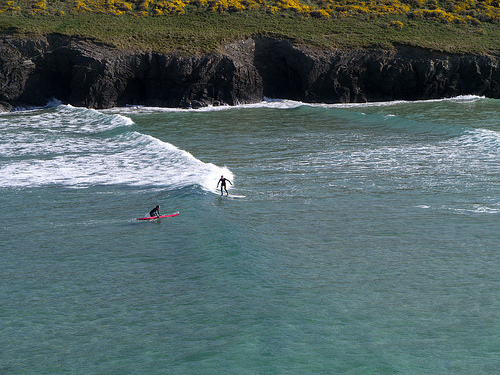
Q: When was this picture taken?
A: During the day.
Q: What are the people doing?
A: Surfing.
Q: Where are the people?
A: In the ocean.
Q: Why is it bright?
A: Its daylight.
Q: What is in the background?
A: Cliffs.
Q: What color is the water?
A: Blue.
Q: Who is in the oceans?
A: The surfers.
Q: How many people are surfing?
A: Two.